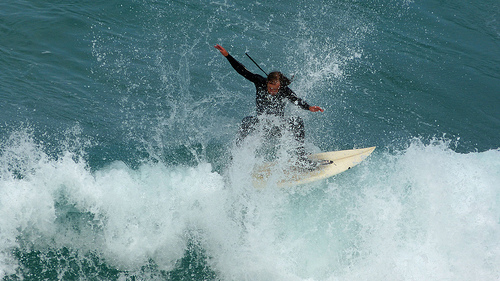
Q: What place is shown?
A: It is an ocean.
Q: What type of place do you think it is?
A: It is an ocean.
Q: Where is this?
A: This is at the ocean.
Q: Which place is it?
A: It is an ocean.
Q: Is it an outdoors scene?
A: Yes, it is outdoors.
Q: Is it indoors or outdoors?
A: It is outdoors.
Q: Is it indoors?
A: No, it is outdoors.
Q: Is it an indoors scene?
A: No, it is outdoors.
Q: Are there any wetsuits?
A: Yes, there is a wetsuit.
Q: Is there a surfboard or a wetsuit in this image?
A: Yes, there is a wetsuit.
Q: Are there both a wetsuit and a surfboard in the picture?
A: Yes, there are both a wetsuit and a surfboard.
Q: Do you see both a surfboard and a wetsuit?
A: Yes, there are both a wetsuit and a surfboard.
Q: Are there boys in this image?
A: No, there are no boys.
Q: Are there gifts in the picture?
A: No, there are no gifts.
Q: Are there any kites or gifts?
A: No, there are no gifts or kites.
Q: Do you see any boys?
A: No, there are no boys.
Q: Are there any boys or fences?
A: No, there are no boys or fences.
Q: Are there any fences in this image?
A: No, there are no fences.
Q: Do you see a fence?
A: No, there are no fences.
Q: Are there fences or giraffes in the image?
A: No, there are no fences or giraffes.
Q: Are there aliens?
A: No, there are no aliens.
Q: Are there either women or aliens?
A: No, there are no aliens or women.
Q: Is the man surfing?
A: Yes, the man is surfing.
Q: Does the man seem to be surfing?
A: Yes, the man is surfing.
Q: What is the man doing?
A: The man is surfing.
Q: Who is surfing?
A: The man is surfing.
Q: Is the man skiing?
A: No, the man is surfing.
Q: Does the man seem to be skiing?
A: No, the man is surfing.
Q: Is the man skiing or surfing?
A: The man is surfing.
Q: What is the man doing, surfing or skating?
A: The man is surfing.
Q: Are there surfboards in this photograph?
A: Yes, there is a surfboard.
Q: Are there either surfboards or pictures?
A: Yes, there is a surfboard.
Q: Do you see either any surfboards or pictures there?
A: Yes, there is a surfboard.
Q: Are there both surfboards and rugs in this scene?
A: No, there is a surfboard but no rugs.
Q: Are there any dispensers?
A: No, there are no dispensers.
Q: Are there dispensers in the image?
A: No, there are no dispensers.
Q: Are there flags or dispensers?
A: No, there are no dispensers or flags.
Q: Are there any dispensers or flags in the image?
A: No, there are no dispensers or flags.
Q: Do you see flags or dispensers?
A: No, there are no dispensers or flags.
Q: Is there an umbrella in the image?
A: No, there are no umbrellas.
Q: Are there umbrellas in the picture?
A: No, there are no umbrellas.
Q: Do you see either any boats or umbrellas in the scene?
A: No, there are no umbrellas or boats.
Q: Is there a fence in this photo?
A: No, there are no fences.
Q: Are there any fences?
A: No, there are no fences.